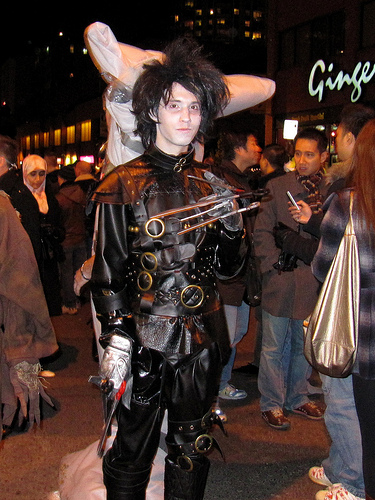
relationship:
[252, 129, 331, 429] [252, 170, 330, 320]
man wearing coat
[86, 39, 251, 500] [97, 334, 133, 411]
guy wearing glove